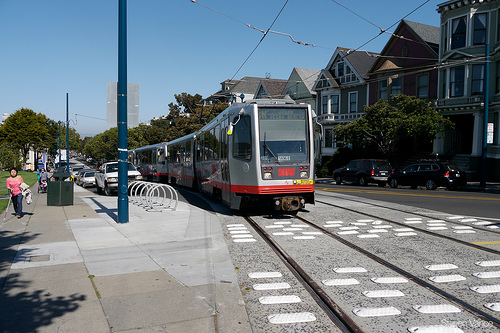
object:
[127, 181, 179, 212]
bike rack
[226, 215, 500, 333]
white rectangles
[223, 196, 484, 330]
road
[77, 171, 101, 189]
cars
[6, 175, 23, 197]
pink shirt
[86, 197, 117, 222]
shadow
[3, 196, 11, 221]
cane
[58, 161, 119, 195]
curb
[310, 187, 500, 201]
yellow line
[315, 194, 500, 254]
street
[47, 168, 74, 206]
garbage can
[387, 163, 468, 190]
black car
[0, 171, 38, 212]
grass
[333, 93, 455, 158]
tree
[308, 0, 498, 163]
houses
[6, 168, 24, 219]
lady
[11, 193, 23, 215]
blue jeans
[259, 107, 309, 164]
front window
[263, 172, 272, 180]
left headlight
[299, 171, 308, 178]
right headlight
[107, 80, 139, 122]
sign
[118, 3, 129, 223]
blue pole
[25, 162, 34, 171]
signs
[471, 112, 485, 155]
pole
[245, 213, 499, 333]
tracks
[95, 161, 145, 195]
truck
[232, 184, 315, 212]
bumper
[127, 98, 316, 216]
car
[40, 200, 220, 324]
sidewalk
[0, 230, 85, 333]
shadows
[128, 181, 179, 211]
rack